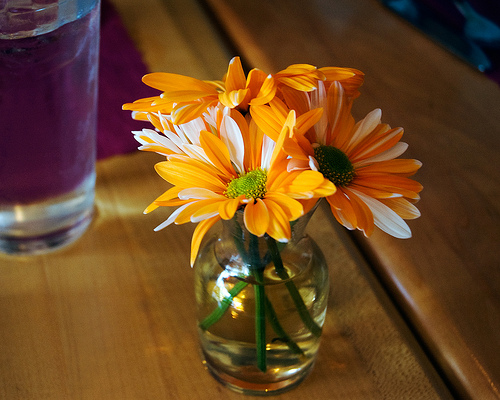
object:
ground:
[440, 167, 500, 285]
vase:
[190, 196, 330, 397]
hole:
[195, 0, 474, 400]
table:
[0, 2, 498, 400]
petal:
[219, 114, 245, 174]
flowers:
[122, 55, 422, 269]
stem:
[249, 232, 267, 373]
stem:
[230, 220, 303, 354]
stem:
[265, 235, 322, 337]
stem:
[198, 221, 298, 331]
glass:
[0, 0, 97, 260]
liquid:
[0, 8, 95, 204]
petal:
[344, 186, 412, 239]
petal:
[243, 198, 269, 238]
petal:
[326, 80, 344, 147]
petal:
[199, 130, 238, 180]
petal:
[190, 215, 220, 268]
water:
[192, 231, 331, 384]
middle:
[224, 168, 267, 198]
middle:
[314, 145, 356, 185]